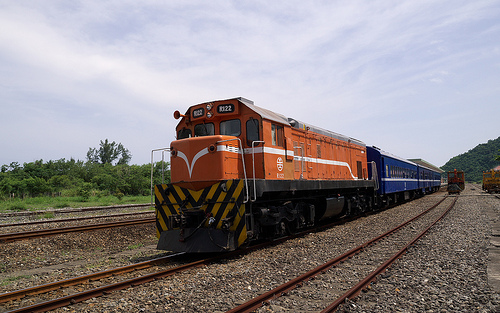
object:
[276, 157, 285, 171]
logo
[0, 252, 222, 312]
track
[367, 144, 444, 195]
train cars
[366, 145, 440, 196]
blue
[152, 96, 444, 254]
train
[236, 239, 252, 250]
train wheel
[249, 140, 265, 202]
railing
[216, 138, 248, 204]
railing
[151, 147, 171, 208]
railing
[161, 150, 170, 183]
railing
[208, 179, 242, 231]
black lines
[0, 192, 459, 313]
gravel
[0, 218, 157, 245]
tracks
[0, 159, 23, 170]
trees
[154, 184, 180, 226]
black lines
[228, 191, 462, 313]
rail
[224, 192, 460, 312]
tracks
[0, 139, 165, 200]
bushes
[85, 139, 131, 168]
tree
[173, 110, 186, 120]
horn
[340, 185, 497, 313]
gravel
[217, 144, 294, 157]
line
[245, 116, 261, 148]
windows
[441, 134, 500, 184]
mountains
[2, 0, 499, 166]
sky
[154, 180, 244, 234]
stripes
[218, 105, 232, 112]
number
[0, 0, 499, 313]
background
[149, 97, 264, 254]
front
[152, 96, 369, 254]
engine